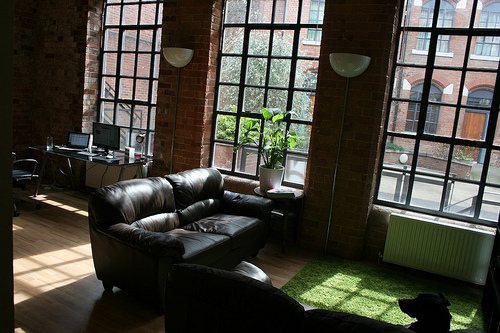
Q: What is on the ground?
A: Rug.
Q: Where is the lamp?
A: Against the wall.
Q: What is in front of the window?
A: Plant.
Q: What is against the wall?
A: White heater.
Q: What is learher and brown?
A: Love seat.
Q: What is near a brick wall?
A: A lamp.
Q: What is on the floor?
A: Carpet.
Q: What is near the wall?
A: A heater.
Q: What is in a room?
A: A black couch.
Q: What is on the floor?
A: A rug.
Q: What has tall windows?
A: A room.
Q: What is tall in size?
A: A lamp.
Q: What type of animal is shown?
A: Dog.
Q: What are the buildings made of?
A: Red brick.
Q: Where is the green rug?
A: In front of the couch.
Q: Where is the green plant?
A: In the middle window.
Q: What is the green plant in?
A: A pot.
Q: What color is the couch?
A: Brown.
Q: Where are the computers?
A: On the desk.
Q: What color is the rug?
A: Green.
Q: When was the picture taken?
A: Daytime.